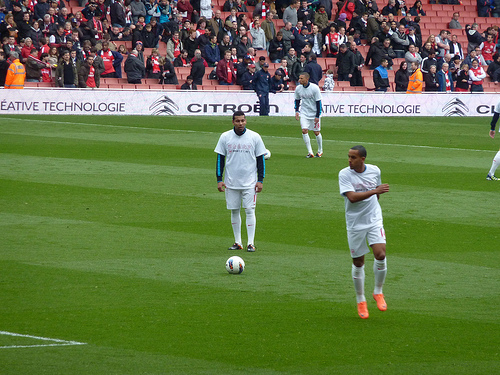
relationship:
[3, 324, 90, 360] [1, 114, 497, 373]
lines are drawn on ground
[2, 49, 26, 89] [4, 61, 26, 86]
guards wearing dress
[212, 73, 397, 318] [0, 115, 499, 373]
soccer players playing on field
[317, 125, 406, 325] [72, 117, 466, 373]
man on a soccer field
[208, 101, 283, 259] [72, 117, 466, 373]
man on a soccer field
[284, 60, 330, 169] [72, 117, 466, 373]
man on a soccer field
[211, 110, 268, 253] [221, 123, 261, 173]
man wearing shirt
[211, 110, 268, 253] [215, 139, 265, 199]
man wearing shirt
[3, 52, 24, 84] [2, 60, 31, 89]
man in coat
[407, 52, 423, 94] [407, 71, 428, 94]
man in coat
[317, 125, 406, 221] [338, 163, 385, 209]
man wearing a shirt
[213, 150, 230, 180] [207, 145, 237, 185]
stripes on a shirt sleeve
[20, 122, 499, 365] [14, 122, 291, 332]
field of grass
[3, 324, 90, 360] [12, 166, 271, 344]
lines on field